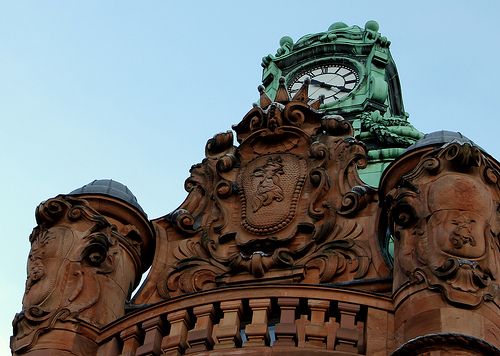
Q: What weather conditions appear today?
A: It is clear.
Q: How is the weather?
A: It is clear.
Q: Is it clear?
A: Yes, it is clear.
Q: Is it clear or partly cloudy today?
A: It is clear.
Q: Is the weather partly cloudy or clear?
A: It is clear.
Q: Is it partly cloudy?
A: No, it is clear.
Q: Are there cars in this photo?
A: No, there are no cars.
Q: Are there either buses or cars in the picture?
A: No, there are no cars or buses.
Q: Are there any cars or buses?
A: No, there are no cars or buses.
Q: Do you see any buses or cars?
A: No, there are no cars or buses.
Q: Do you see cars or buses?
A: No, there are no cars or buses.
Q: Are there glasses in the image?
A: No, there are no glasses.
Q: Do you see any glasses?
A: No, there are no glasses.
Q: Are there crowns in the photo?
A: Yes, there is a crown.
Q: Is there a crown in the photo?
A: Yes, there is a crown.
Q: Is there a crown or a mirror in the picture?
A: Yes, there is a crown.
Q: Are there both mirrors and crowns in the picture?
A: No, there is a crown but no mirrors.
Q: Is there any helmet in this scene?
A: No, there are no helmets.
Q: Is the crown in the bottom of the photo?
A: No, the crown is in the top of the image.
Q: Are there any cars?
A: No, there are no cars.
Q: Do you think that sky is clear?
A: Yes, the sky is clear.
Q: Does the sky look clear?
A: Yes, the sky is clear.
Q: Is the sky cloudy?
A: No, the sky is clear.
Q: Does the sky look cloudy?
A: No, the sky is clear.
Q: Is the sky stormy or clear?
A: The sky is clear.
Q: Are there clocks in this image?
A: Yes, there is a clock.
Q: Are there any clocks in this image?
A: Yes, there is a clock.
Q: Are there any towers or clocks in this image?
A: Yes, there is a clock.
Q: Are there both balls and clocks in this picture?
A: Yes, there are both a clock and a ball.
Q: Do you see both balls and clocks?
A: Yes, there are both a clock and a ball.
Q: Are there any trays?
A: No, there are no trays.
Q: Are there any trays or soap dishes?
A: No, there are no trays or soap dishes.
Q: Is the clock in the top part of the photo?
A: Yes, the clock is in the top of the image.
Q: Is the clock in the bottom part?
A: No, the clock is in the top of the image.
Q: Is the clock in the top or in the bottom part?
A: The clock is in the top of the image.